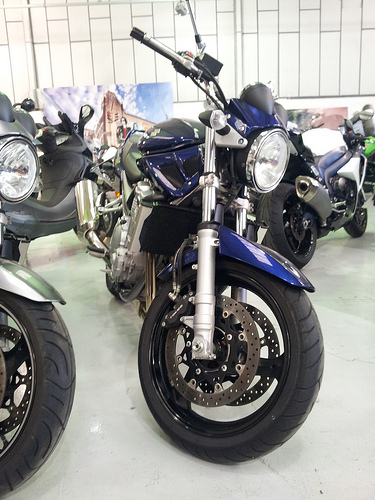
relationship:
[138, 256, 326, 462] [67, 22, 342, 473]
front tire on motorcycle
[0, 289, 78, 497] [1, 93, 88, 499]
front tire on motorcycle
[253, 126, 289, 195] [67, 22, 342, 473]
headlights on motorcycle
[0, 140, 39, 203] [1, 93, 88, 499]
headlights on motorcycle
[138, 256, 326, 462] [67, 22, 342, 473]
tire on motorcycle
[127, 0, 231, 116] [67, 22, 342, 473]
handle bar on motorcycle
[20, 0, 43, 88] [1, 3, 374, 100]
bar on window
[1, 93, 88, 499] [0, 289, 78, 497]
motorcycle has a front tire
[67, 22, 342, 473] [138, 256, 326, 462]
motorcycle has a tire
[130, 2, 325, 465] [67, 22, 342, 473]
front end of motorcycle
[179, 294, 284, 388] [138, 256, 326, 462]
spokes on tire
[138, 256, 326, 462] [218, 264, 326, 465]
tire has a part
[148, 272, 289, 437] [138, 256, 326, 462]
rim of tire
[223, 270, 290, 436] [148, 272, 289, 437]
part of rim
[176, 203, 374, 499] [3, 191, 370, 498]
part of floor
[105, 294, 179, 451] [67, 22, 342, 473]
shadow of motorcycle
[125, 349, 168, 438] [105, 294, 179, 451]
part of shadow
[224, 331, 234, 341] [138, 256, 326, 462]
bolt on tire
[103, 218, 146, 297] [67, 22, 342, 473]
engine on motorcycle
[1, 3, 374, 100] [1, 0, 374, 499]
window behind bikes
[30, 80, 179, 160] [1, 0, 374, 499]
painting behind bikes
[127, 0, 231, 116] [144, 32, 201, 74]
handle bar has a break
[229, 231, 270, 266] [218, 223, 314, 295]
reflection on fender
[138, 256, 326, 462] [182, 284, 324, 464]
tire has treads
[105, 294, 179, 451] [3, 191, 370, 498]
shadow on floor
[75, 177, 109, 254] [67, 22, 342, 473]
pipe on motorcycle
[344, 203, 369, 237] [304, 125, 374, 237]
back tire on motorcycle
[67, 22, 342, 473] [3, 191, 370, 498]
motorcycle on floor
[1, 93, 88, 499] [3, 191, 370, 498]
motorcycle on floor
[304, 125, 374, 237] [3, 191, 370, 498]
motorcycle on floor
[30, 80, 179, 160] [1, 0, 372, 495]
painting in garage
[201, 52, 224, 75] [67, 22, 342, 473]
dial on motorcycle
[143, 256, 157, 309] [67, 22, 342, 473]
shock on motorcycle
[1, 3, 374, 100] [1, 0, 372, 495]
window in garage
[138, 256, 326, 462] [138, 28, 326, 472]
tire on front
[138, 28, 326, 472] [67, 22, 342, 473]
front of motorcycle